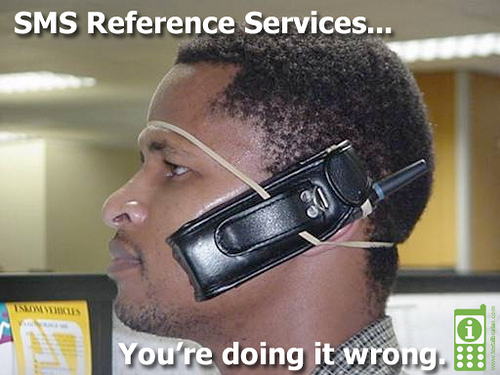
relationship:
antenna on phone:
[372, 158, 429, 200] [165, 137, 425, 300]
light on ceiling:
[0, 69, 96, 94] [0, 0, 497, 140]